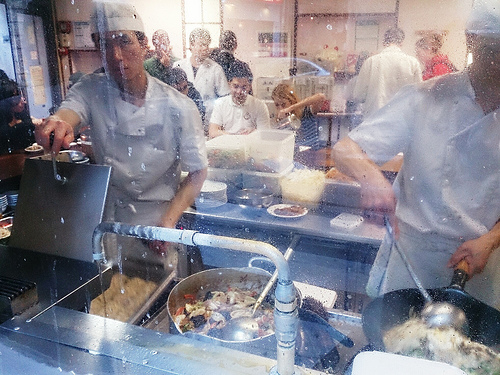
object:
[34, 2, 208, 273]
man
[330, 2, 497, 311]
man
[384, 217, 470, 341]
spoon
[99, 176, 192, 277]
apron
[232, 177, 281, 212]
bowl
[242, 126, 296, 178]
container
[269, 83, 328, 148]
woman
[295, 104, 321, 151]
shirt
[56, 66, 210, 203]
shirt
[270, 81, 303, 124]
hair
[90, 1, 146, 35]
hat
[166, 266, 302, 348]
pot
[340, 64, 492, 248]
uniform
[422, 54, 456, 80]
cloth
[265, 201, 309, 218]
plate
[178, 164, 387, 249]
counter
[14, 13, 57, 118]
door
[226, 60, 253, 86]
hair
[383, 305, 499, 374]
food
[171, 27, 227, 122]
people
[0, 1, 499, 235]
restaurant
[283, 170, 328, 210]
food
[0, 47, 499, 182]
area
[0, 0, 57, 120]
doorway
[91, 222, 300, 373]
faucet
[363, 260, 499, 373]
pan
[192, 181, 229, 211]
plates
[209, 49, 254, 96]
shirt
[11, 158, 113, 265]
lid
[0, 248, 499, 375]
cooker